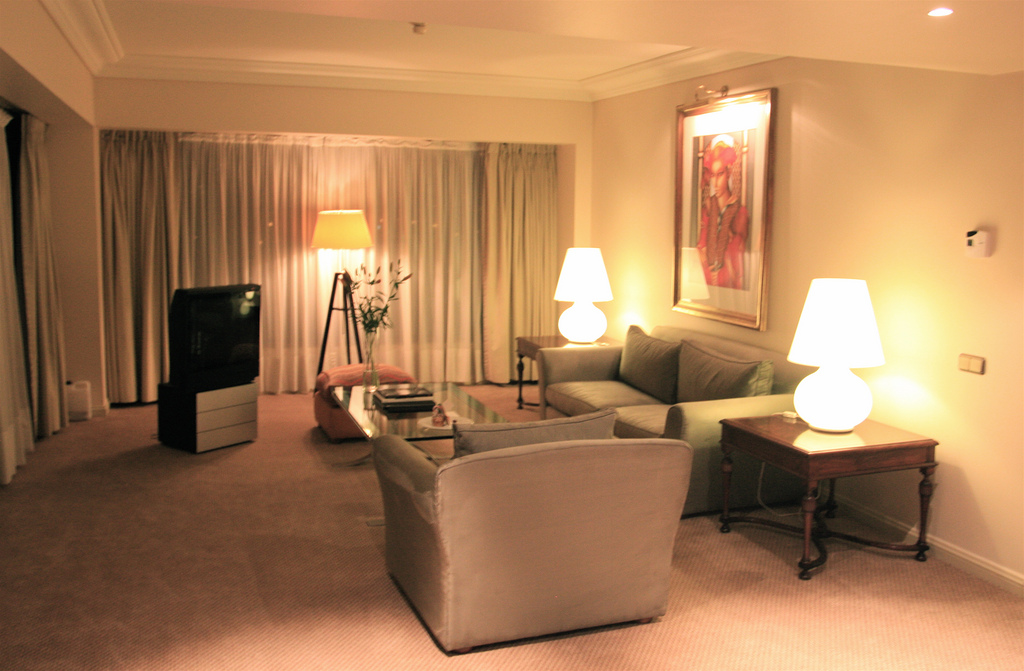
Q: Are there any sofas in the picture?
A: Yes, there is a sofa.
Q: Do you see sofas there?
A: Yes, there is a sofa.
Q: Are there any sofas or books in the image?
A: Yes, there is a sofa.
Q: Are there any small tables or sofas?
A: Yes, there is a small sofa.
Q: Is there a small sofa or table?
A: Yes, there is a small sofa.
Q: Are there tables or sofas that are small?
A: Yes, the sofa is small.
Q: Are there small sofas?
A: Yes, there is a small sofa.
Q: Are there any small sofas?
A: Yes, there is a small sofa.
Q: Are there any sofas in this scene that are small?
A: Yes, there is a small sofa.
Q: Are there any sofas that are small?
A: Yes, there is a sofa that is small.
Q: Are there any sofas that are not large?
A: Yes, there is a small sofa.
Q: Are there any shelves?
A: No, there are no shelves.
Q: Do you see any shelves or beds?
A: No, there are no shelves or beds.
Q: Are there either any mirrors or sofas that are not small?
A: No, there is a sofa but it is small.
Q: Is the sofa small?
A: Yes, the sofa is small.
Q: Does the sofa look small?
A: Yes, the sofa is small.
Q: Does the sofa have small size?
A: Yes, the sofa is small.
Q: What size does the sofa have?
A: The sofa has small size.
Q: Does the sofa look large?
A: No, the sofa is small.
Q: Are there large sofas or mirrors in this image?
A: No, there is a sofa but it is small.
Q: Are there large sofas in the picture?
A: No, there is a sofa but it is small.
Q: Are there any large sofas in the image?
A: No, there is a sofa but it is small.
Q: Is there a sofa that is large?
A: No, there is a sofa but it is small.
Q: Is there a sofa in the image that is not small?
A: No, there is a sofa but it is small.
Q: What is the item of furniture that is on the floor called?
A: The piece of furniture is a sofa.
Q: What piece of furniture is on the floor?
A: The piece of furniture is a sofa.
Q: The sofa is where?
A: The sofa is on the floor.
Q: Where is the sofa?
A: The sofa is on the floor.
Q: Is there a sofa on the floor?
A: Yes, there is a sofa on the floor.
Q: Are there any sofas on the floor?
A: Yes, there is a sofa on the floor.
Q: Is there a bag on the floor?
A: No, there is a sofa on the floor.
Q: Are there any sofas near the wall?
A: Yes, there is a sofa near the wall.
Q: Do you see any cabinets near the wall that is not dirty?
A: No, there is a sofa near the wall.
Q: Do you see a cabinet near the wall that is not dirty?
A: No, there is a sofa near the wall.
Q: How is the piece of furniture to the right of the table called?
A: The piece of furniture is a sofa.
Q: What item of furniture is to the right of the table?
A: The piece of furniture is a sofa.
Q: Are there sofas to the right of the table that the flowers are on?
A: Yes, there is a sofa to the right of the table.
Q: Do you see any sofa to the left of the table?
A: No, the sofa is to the right of the table.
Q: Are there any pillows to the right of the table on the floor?
A: No, there is a sofa to the right of the table.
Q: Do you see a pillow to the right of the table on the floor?
A: No, there is a sofa to the right of the table.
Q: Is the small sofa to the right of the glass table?
A: Yes, the sofa is to the right of the table.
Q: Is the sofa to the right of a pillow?
A: No, the sofa is to the right of the table.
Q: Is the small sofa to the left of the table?
A: No, the sofa is to the right of the table.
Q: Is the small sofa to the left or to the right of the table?
A: The sofa is to the right of the table.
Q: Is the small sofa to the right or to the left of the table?
A: The sofa is to the right of the table.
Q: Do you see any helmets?
A: No, there are no helmets.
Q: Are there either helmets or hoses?
A: No, there are no helmets or hoses.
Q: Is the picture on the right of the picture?
A: Yes, the picture is on the right of the image.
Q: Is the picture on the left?
A: No, the picture is on the right of the image.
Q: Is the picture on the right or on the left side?
A: The picture is on the right of the image.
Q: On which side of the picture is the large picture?
A: The picture is on the right of the image.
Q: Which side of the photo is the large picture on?
A: The picture is on the right of the image.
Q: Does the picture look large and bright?
A: Yes, the picture is large and bright.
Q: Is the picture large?
A: Yes, the picture is large.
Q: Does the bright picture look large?
A: Yes, the picture is large.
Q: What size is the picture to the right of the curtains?
A: The picture is large.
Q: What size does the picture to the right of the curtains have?
A: The picture has large size.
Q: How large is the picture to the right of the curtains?
A: The picture is large.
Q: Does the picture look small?
A: No, the picture is large.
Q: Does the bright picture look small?
A: No, the picture is large.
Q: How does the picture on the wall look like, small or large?
A: The picture is large.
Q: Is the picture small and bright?
A: No, the picture is bright but large.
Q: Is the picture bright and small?
A: No, the picture is bright but large.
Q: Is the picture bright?
A: Yes, the picture is bright.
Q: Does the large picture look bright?
A: Yes, the picture is bright.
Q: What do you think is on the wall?
A: The picture is on the wall.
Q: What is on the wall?
A: The picture is on the wall.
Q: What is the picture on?
A: The picture is on the wall.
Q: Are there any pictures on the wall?
A: Yes, there is a picture on the wall.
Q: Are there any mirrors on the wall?
A: No, there is a picture on the wall.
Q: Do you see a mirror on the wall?
A: No, there is a picture on the wall.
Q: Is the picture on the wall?
A: Yes, the picture is on the wall.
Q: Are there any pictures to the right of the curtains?
A: Yes, there is a picture to the right of the curtains.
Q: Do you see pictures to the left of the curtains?
A: No, the picture is to the right of the curtains.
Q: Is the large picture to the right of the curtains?
A: Yes, the picture is to the right of the curtains.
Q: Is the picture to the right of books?
A: No, the picture is to the right of the curtains.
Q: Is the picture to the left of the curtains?
A: No, the picture is to the right of the curtains.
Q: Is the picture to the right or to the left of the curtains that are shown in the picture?
A: The picture is to the right of the curtains.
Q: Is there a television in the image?
A: Yes, there is a television.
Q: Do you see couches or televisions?
A: Yes, there is a television.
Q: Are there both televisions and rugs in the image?
A: No, there is a television but no rugs.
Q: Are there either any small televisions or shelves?
A: Yes, there is a small television.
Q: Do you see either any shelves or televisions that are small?
A: Yes, the television is small.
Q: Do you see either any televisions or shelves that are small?
A: Yes, the television is small.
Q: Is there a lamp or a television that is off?
A: Yes, the television is off.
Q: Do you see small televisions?
A: Yes, there is a small television.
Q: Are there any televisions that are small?
A: Yes, there is a television that is small.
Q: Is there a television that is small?
A: Yes, there is a television that is small.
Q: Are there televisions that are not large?
A: Yes, there is a small television.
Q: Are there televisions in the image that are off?
A: Yes, there is a television that is off.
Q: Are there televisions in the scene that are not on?
A: Yes, there is a television that is off.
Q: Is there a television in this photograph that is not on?
A: Yes, there is a television that is off.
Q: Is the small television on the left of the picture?
A: Yes, the television is on the left of the image.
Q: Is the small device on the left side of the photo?
A: Yes, the television is on the left of the image.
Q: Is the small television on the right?
A: No, the television is on the left of the image.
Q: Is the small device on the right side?
A: No, the television is on the left of the image.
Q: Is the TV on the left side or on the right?
A: The TV is on the left of the image.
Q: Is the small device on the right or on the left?
A: The TV is on the left of the image.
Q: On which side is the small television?
A: The TV is on the left of the image.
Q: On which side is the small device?
A: The TV is on the left of the image.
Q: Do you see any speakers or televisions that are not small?
A: No, there is a television but it is small.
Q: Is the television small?
A: Yes, the television is small.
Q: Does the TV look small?
A: Yes, the TV is small.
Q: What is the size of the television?
A: The television is small.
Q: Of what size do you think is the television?
A: The television is small.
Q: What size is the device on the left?
A: The television is small.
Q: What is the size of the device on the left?
A: The television is small.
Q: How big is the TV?
A: The TV is small.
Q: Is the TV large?
A: No, the TV is small.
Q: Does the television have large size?
A: No, the television is small.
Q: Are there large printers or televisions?
A: No, there is a television but it is small.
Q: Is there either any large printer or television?
A: No, there is a television but it is small.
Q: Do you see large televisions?
A: No, there is a television but it is small.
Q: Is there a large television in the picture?
A: No, there is a television but it is small.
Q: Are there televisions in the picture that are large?
A: No, there is a television but it is small.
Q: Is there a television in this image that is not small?
A: No, there is a television but it is small.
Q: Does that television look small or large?
A: The television is small.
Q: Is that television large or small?
A: The television is small.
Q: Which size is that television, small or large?
A: The television is small.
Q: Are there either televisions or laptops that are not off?
A: No, there is a television but it is off.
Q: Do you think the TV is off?
A: Yes, the TV is off.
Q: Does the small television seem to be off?
A: Yes, the TV is off.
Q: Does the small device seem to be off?
A: Yes, the TV is off.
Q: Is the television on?
A: No, the television is off.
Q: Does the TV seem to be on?
A: No, the TV is off.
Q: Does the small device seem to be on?
A: No, the TV is off.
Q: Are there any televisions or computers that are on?
A: No, there is a television but it is off.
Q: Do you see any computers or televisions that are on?
A: No, there is a television but it is off.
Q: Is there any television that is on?
A: No, there is a television but it is off.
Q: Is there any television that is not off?
A: No, there is a television but it is off.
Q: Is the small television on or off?
A: The television is off.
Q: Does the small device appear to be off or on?
A: The television is off.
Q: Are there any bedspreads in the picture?
A: No, there are no bedspreads.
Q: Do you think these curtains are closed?
A: Yes, the curtains are closed.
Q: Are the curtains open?
A: No, the curtains are closed.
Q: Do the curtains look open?
A: No, the curtains are closed.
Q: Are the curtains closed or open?
A: The curtains are closed.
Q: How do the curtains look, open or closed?
A: The curtains are closed.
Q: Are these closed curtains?
A: Yes, these are closed curtains.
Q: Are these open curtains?
A: No, these are closed curtains.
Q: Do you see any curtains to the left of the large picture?
A: Yes, there are curtains to the left of the picture.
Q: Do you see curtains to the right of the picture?
A: No, the curtains are to the left of the picture.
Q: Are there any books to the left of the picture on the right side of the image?
A: No, there are curtains to the left of the picture.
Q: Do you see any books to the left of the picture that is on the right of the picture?
A: No, there are curtains to the left of the picture.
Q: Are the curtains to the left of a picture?
A: Yes, the curtains are to the left of a picture.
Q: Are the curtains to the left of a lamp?
A: No, the curtains are to the left of a picture.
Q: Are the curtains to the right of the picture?
A: No, the curtains are to the left of the picture.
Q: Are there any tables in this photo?
A: Yes, there is a table.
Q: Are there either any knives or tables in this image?
A: Yes, there is a table.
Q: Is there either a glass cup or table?
A: Yes, there is a glass table.